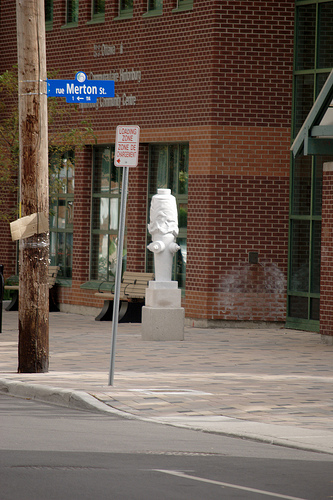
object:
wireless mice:
[94, 265, 163, 306]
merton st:
[66, 84, 107, 96]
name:
[54, 82, 106, 95]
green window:
[293, 3, 332, 71]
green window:
[291, 70, 331, 142]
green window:
[289, 138, 323, 218]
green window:
[287, 217, 323, 296]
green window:
[287, 291, 319, 328]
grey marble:
[142, 184, 185, 343]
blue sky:
[48, 70, 120, 109]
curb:
[1, 383, 108, 414]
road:
[0, 383, 332, 500]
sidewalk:
[1, 315, 331, 444]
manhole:
[140, 448, 225, 457]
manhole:
[8, 461, 110, 471]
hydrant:
[147, 186, 178, 286]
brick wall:
[0, 1, 288, 324]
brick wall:
[187, 175, 208, 325]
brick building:
[42, 6, 325, 332]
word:
[123, 92, 136, 106]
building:
[1, 1, 290, 321]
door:
[288, 149, 324, 327]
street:
[0, 395, 333, 500]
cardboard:
[9, 210, 48, 240]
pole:
[11, 3, 48, 376]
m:
[67, 83, 74, 94]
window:
[296, 4, 314, 71]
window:
[291, 74, 313, 137]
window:
[288, 141, 310, 216]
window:
[289, 215, 309, 294]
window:
[287, 293, 309, 320]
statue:
[138, 185, 186, 345]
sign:
[115, 125, 138, 170]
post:
[107, 164, 126, 387]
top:
[157, 187, 171, 194]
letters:
[66, 83, 99, 96]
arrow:
[77, 96, 84, 101]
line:
[148, 458, 308, 500]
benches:
[94, 268, 164, 326]